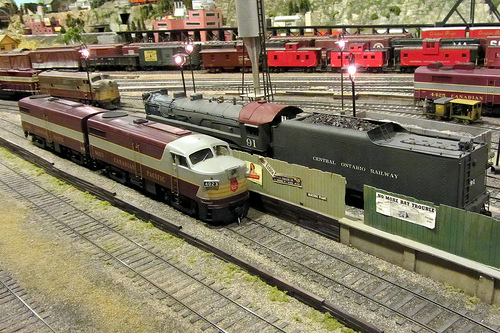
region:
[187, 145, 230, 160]
2 windows on front of train car.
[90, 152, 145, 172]
Maroon coloring on bottom of train.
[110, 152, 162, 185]
Yellow words on side of train.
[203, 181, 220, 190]
White numbers on front of train.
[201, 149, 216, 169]
Wiper on front window.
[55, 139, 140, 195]
Bottom of train is black.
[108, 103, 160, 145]
Top of train car is maroon.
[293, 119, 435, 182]
Train car is black.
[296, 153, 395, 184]
White words on side of train car.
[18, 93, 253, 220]
two train cars on the track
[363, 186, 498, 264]
a green fence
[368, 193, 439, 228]
a white poster on the fence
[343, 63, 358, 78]
the light is on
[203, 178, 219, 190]
the train number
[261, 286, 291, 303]
a patch of grass by the track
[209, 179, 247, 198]
yellow lines on the train bumper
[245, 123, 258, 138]
window on the train cart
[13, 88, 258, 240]
a small train in track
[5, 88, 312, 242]
a train in track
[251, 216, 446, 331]
a long rail way track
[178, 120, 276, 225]
front part of train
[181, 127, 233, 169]
window of the train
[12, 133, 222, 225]
wheel of the train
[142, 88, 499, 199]
another train on track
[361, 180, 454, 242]
a board in the train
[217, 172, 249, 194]
red circle in train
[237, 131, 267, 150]
number printed on side of train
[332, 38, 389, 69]
red train on tracks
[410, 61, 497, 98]
maroon train on tracks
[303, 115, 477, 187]
black train on tracks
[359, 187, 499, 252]
green wall in between tracks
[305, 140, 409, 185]
logo on side of black train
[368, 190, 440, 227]
white poster on green wall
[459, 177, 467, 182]
part of a container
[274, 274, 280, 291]
part of a rail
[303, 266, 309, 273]
edge of a rail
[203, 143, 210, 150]
part of a window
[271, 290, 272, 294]
edge of a rail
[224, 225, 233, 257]
part of a train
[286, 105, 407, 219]
a train car on the track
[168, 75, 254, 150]
a train car on the track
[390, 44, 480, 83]
a train car on the track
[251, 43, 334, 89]
a train car on the track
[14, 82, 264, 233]
red and grey train on tracks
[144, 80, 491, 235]
red and grey train on tracks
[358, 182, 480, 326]
green fence by train tracks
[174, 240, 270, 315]
green grass by train tracks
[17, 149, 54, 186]
green grass by train tracks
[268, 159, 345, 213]
back and white signs on fence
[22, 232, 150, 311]
brown dead by train tracks